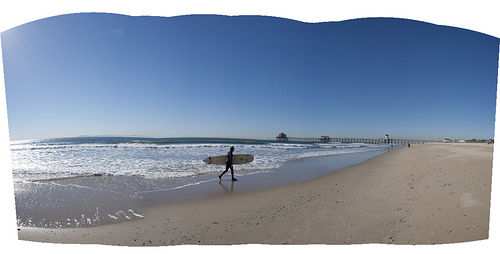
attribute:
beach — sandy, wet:
[205, 139, 486, 249]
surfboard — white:
[201, 150, 258, 167]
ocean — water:
[16, 133, 220, 175]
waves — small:
[23, 140, 320, 178]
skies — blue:
[3, 13, 495, 133]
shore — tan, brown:
[158, 163, 490, 236]